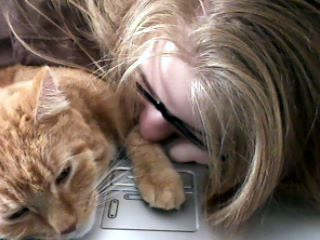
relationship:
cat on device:
[4, 64, 189, 240] [39, 160, 217, 240]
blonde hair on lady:
[9, 0, 313, 237] [124, 28, 237, 177]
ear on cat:
[33, 67, 66, 118] [4, 64, 189, 240]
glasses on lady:
[128, 76, 217, 152] [124, 28, 237, 177]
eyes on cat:
[4, 162, 86, 230] [4, 64, 189, 240]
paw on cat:
[135, 154, 185, 211] [4, 64, 189, 240]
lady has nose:
[124, 28, 237, 177] [139, 109, 172, 140]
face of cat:
[4, 151, 102, 239] [4, 64, 189, 240]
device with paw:
[39, 160, 217, 240] [135, 154, 185, 211]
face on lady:
[118, 48, 220, 166] [124, 28, 237, 177]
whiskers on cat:
[85, 165, 138, 211] [4, 64, 189, 240]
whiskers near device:
[85, 165, 138, 211] [39, 160, 217, 240]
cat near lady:
[4, 64, 189, 240] [124, 28, 237, 177]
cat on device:
[4, 64, 189, 240] [96, 168, 202, 232]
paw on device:
[135, 154, 185, 211] [96, 168, 202, 232]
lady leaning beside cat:
[124, 28, 237, 177] [4, 64, 189, 240]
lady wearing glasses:
[124, 28, 237, 177] [128, 76, 217, 152]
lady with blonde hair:
[124, 28, 237, 177] [9, 0, 313, 237]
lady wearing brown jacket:
[124, 28, 237, 177] [2, 0, 106, 63]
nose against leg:
[139, 109, 172, 140] [121, 119, 193, 212]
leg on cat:
[121, 119, 193, 212] [4, 64, 189, 240]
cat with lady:
[4, 64, 189, 240] [124, 28, 237, 177]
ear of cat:
[33, 67, 66, 118] [4, 64, 189, 240]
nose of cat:
[39, 198, 91, 236] [4, 64, 189, 240]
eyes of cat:
[4, 162, 86, 230] [4, 64, 189, 240]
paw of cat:
[135, 154, 185, 211] [4, 64, 189, 240]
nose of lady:
[139, 109, 172, 140] [124, 28, 237, 177]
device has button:
[96, 168, 202, 232] [107, 195, 123, 222]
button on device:
[107, 195, 123, 222] [39, 160, 217, 240]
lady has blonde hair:
[124, 28, 237, 177] [9, 0, 313, 237]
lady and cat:
[124, 28, 237, 177] [4, 64, 189, 240]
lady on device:
[124, 28, 237, 177] [96, 168, 202, 232]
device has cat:
[96, 168, 202, 232] [4, 64, 189, 240]